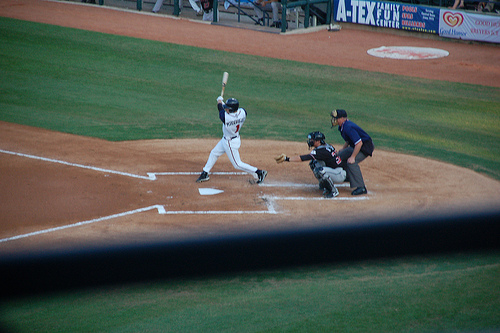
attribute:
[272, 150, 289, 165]
glove — leather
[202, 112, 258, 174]
uniform — white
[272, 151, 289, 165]
brown glove — leather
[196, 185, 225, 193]
home plate — white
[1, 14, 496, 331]
grass — green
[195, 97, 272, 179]
uniform — white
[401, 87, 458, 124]
grass — green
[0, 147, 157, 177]
line — white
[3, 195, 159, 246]
line — white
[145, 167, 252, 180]
line — white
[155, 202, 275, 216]
line — white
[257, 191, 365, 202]
line — white